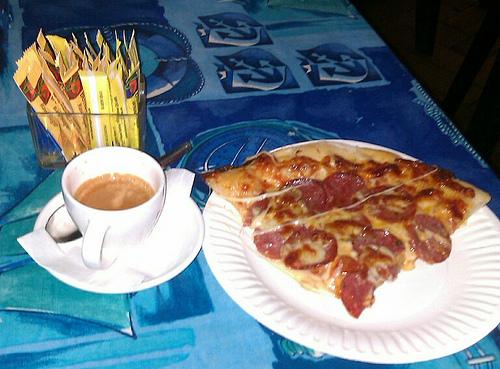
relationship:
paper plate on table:
[203, 247, 388, 363] [12, 10, 466, 222]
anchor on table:
[229, 58, 287, 91] [0, 0, 500, 369]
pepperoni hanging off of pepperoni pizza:
[327, 232, 369, 322] [201, 147, 490, 319]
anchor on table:
[228, 54, 287, 91] [0, 0, 500, 369]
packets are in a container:
[121, 63, 141, 148] [25, 78, 150, 168]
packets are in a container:
[75, 68, 112, 150] [25, 78, 150, 168]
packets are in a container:
[13, 62, 68, 155] [25, 78, 150, 168]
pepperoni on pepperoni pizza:
[283, 230, 338, 268] [201, 147, 490, 319]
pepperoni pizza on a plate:
[201, 147, 490, 319] [203, 139, 498, 364]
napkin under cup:
[55, 159, 172, 284] [59, 145, 169, 281]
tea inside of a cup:
[71, 170, 155, 207] [56, 153, 191, 258]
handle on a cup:
[82, 224, 129, 275] [62, 143, 165, 276]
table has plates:
[0, 0, 500, 369] [38, 150, 494, 295]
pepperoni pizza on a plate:
[201, 140, 492, 320] [203, 139, 498, 364]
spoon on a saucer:
[44, 137, 196, 239] [30, 185, 206, 294]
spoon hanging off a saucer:
[44, 141, 192, 243] [29, 192, 211, 303]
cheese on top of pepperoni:
[410, 174, 459, 224] [306, 168, 378, 219]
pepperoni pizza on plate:
[201, 147, 490, 319] [328, 279, 495, 366]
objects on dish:
[61, 53, 116, 84] [7, 109, 142, 138]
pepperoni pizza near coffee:
[201, 147, 490, 319] [32, 145, 204, 294]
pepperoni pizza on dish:
[201, 147, 490, 319] [200, 138, 500, 352]